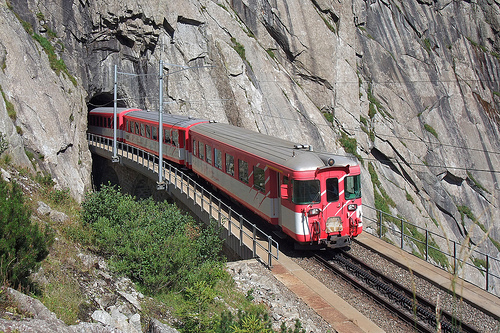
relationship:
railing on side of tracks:
[86, 131, 282, 267] [343, 231, 458, 331]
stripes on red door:
[317, 174, 351, 210] [321, 169, 346, 234]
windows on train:
[192, 140, 290, 188] [94, 107, 375, 267]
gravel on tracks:
[325, 240, 499, 330] [324, 251, 474, 331]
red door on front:
[321, 169, 346, 234] [290, 161, 362, 251]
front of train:
[290, 161, 362, 251] [85, 103, 367, 255]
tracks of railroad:
[246, 183, 497, 327] [86, 101, 496, 327]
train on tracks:
[85, 103, 367, 255] [299, 247, 498, 332]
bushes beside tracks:
[81, 181, 213, 308] [319, 253, 484, 331]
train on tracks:
[85, 103, 367, 255] [316, 245, 474, 332]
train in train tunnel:
[85, 103, 367, 255] [82, 90, 130, 158]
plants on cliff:
[375, 191, 455, 274] [287, 24, 490, 245]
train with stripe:
[85, 103, 367, 255] [153, 148, 314, 233]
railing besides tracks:
[182, 173, 254, 253] [313, 249, 497, 333]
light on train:
[309, 208, 321, 220] [188, 107, 373, 257]